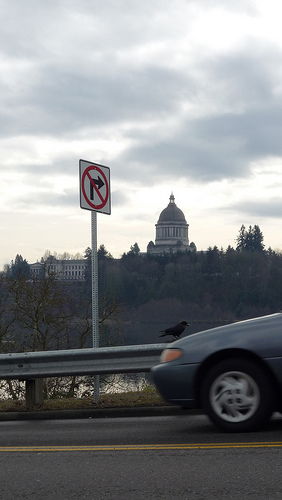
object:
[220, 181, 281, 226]
cloud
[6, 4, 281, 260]
sky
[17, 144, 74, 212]
cloud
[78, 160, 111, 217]
sign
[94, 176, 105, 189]
arrow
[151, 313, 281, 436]
car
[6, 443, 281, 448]
line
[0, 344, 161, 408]
railing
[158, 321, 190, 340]
bird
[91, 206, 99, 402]
pole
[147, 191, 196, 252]
building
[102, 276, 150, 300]
trees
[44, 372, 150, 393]
water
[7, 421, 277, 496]
road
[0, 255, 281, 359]
hill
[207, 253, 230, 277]
leaves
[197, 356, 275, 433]
tire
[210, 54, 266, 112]
cloud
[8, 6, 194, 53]
cloud